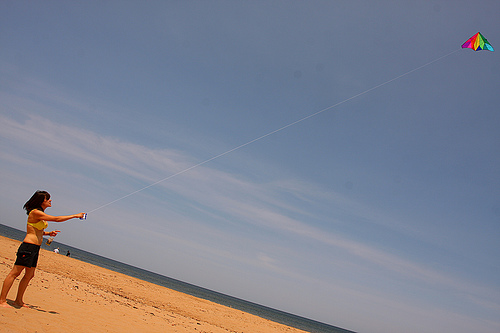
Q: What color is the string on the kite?
A: White.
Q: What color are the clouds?
A: White.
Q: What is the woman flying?
A: Kite.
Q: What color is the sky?
A: Blue.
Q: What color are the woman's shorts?
A: Black.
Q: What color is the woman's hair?
A: Black.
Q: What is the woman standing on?
A: Sand.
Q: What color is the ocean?
A: Blue.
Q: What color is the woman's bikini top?
A: Yellow.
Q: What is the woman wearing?
A: Bikini top and shorts.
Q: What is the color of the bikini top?
A: Yellow.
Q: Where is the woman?
A: At the beach.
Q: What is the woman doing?
A: Flying a kite.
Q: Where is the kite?
A: Up in the air.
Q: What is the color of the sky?
A: Blue.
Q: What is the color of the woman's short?
A: Black.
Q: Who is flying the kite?
A: The woman.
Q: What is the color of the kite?
A: Purple, blue, pink, yellow and green.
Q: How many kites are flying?
A: 1.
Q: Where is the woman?
A: On a beach.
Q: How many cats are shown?
A: Zero.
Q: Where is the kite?
A: In the air.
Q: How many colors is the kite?
A: Five.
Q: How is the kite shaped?
A: Triangular.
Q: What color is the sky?
A: Blue.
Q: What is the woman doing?
A: Flying a kite.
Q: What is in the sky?
A: Clouds.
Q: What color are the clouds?
A: White.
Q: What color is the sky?
A: Blue.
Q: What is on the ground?
A: Sand.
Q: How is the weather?
A: Sunny.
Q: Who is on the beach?
A: A woman.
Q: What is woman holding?
A: A kite.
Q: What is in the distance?
A: Water.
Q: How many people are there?
A: One.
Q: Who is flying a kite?
A: The woman.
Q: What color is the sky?
A: Blue.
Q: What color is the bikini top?
A: Yellow.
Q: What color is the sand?
A: Brown.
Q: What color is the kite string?
A: White.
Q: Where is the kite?
A: In the sky.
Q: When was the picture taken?
A: Daytime.